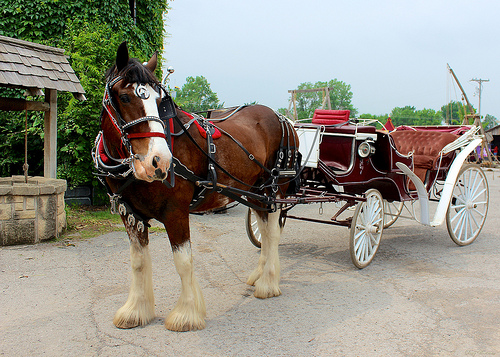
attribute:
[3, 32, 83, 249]
well — stone, shingled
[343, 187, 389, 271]
wheel — white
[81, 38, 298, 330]
horse — brown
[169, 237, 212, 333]
leg — white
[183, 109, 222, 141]
saddle — red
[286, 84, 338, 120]
frame — wood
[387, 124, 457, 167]
seat — red, brown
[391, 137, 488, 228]
footpiece — white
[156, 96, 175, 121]
blinders — black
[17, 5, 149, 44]
vines — green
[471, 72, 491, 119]
pole — tall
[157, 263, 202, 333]
feet — white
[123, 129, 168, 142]
strap — red